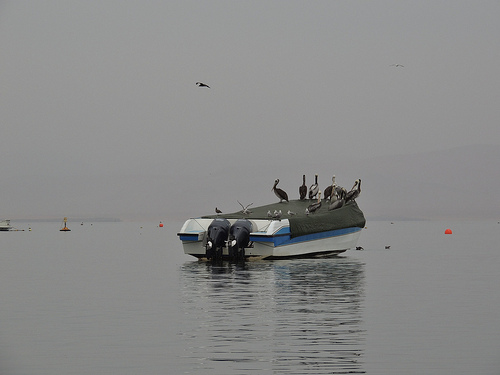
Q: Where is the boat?
A: In the water.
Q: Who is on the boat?
A: Birds.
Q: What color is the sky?
A: Gray.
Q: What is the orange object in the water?
A: Buoy.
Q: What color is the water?
A: Gray water.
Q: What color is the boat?
A: Blue and white.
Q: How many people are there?
A: None.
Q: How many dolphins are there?
A: No dolphins.